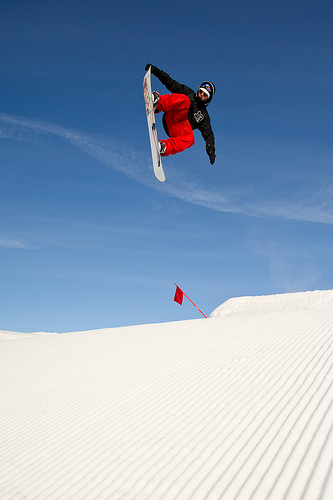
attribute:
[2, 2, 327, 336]
sky — blue , clear , white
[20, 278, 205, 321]
sky — clear , blue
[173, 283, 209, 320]
flag — red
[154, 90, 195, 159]
pants — red 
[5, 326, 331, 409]
snow — grooves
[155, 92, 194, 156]
snow pants — red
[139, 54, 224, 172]
person — snowboarding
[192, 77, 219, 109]
head — hooded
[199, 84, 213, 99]
hat — white, billed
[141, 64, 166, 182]
snowboard — white